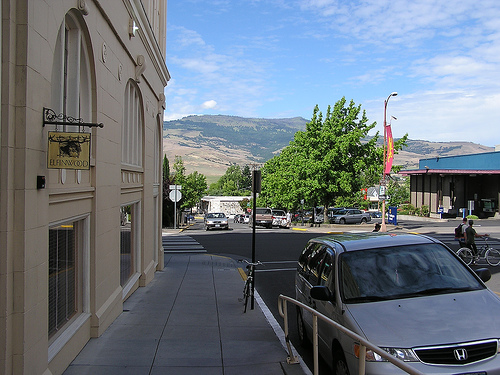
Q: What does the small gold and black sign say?
A: Elfinwood.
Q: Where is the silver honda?
A: Parked on the street.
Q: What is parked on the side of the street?
A: A silver honda.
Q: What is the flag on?
A: A pole.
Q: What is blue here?
A: The sky.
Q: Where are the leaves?
A: On the trees.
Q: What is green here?
A: The trees.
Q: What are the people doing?
A: Crossing the street.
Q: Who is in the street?
A: Some people.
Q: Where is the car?
A: On the street.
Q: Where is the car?
A: At the curb.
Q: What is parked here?
A: The car.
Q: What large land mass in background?
A: Mountain.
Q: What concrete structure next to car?
A: Sidewalk.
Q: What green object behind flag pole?
A: Tree.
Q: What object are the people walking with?
A: Bicycle.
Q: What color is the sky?
A: Blue.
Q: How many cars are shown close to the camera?
A: One.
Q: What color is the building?
A: Beige.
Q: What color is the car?
A: Silver.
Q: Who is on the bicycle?
A: A man.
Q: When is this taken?
A: During the day.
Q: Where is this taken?
A: Outside somewhere with mountains.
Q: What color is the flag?
A: Red and yellow.